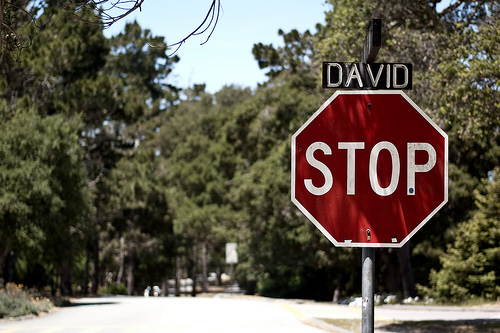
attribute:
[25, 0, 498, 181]
blue sky — clear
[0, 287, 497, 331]
road — asphalt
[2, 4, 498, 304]
trees — green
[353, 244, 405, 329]
pole — metal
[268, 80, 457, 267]
stop sign — red, white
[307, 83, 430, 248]
sign — red 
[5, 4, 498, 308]
grove — thick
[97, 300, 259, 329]
road — light grey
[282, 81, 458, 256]
octagon — red, white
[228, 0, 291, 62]
sky — cloudless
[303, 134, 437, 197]
white letters — white 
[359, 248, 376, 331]
pole — grey 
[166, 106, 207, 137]
trees — green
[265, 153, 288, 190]
trees — green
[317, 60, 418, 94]
name — David